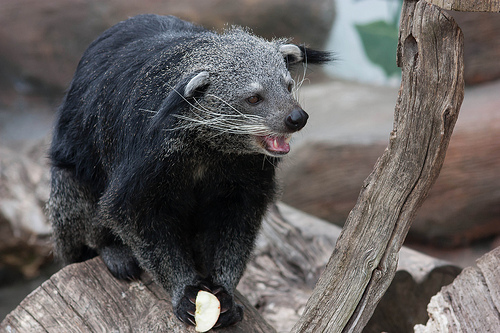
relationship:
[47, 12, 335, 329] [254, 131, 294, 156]
binturong has mouth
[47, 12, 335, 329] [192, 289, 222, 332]
binturong holding apple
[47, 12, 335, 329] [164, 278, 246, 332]
binturong has paws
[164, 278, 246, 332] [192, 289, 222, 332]
paws holding apple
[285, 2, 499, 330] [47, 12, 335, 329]
branch next to binturong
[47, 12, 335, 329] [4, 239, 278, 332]
binturong on top of wood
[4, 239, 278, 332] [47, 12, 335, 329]
wood underneath binturong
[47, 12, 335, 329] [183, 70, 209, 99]
binturong has ear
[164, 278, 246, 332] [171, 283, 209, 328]
paws have paws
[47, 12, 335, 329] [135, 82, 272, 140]
binturong has whiskers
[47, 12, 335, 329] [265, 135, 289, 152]
binturong has tongue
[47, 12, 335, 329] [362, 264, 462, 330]
binturong as shadow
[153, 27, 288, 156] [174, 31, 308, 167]
sand on top of head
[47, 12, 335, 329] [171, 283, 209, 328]
binturong has paws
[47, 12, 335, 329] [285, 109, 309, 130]
binturong has nose